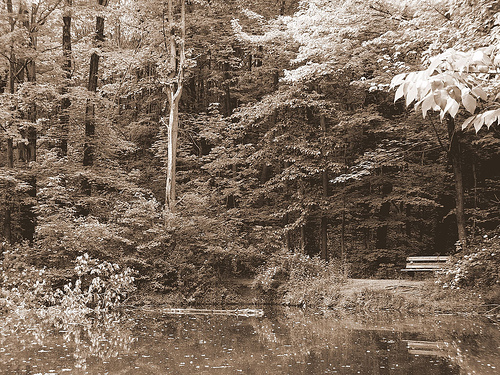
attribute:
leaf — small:
[115, 216, 122, 222]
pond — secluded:
[2, 299, 494, 371]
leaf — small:
[333, 176, 345, 184]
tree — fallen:
[0, 272, 264, 344]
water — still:
[5, 297, 497, 374]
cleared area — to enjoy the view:
[336, 253, 454, 302]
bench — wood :
[398, 245, 473, 290]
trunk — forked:
[146, 124, 195, 189]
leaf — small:
[196, 196, 263, 261]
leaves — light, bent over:
[417, 58, 491, 124]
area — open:
[303, 254, 442, 312]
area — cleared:
[318, 251, 445, 315]